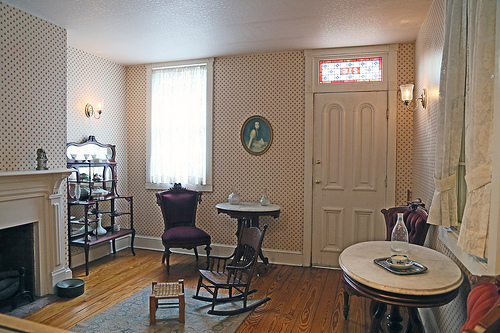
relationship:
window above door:
[316, 59, 385, 85] [307, 89, 392, 266]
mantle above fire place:
[1, 148, 82, 183] [0, 160, 90, 302]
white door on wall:
[313, 99, 385, 252] [250, 58, 425, 258]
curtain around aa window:
[431, 0, 499, 275] [452, 23, 485, 170]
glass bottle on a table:
[386, 212, 414, 272] [332, 234, 469, 331]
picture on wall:
[238, 115, 273, 155] [119, 49, 305, 254]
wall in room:
[119, 49, 305, 254] [5, 4, 467, 324]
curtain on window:
[149, 68, 207, 185] [139, 60, 222, 197]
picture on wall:
[238, 115, 273, 155] [216, 52, 302, 249]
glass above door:
[319, 55, 384, 85] [307, 89, 392, 266]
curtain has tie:
[423, 4, 498, 260] [463, 167, 485, 204]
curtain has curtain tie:
[431, 0, 499, 275] [430, 172, 465, 197]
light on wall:
[388, 80, 435, 112] [241, 98, 315, 182]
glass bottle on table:
[389, 212, 410, 255] [287, 215, 452, 317]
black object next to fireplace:
[48, 276, 85, 301] [3, 171, 68, 330]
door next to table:
[307, 89, 392, 266] [338, 240, 464, 331]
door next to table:
[307, 89, 392, 266] [214, 200, 281, 264]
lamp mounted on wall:
[82, 96, 110, 122] [64, 65, 131, 255]